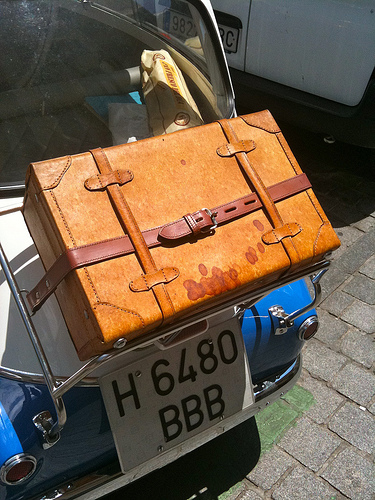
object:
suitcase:
[18, 108, 343, 360]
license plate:
[97, 316, 255, 473]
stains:
[179, 219, 265, 302]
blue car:
[0, 1, 339, 500]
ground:
[322, 120, 338, 145]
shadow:
[230, 73, 374, 228]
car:
[120, 1, 372, 109]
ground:
[215, 119, 374, 498]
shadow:
[95, 414, 261, 498]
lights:
[2, 453, 38, 485]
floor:
[27, 18, 165, 134]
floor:
[264, 379, 373, 499]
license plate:
[163, 10, 242, 54]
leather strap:
[24, 172, 313, 304]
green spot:
[240, 376, 317, 454]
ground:
[229, 255, 375, 500]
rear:
[0, 0, 318, 496]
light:
[302, 321, 320, 344]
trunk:
[0, 149, 320, 439]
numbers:
[148, 329, 238, 398]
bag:
[137, 49, 205, 132]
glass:
[2, 1, 233, 184]